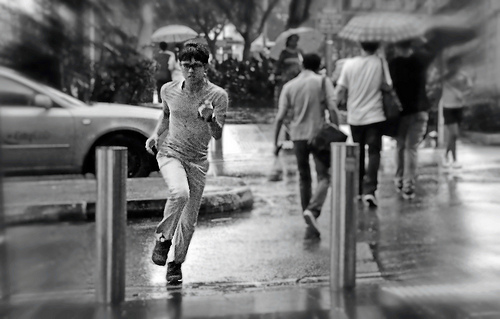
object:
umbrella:
[336, 13, 430, 45]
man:
[333, 38, 408, 209]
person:
[268, 32, 309, 87]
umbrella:
[269, 26, 325, 65]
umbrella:
[148, 24, 200, 44]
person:
[152, 39, 176, 105]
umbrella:
[421, 24, 478, 49]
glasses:
[180, 61, 207, 70]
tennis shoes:
[151, 236, 173, 266]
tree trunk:
[242, 40, 253, 67]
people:
[383, 30, 438, 201]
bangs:
[178, 46, 209, 63]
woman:
[429, 49, 476, 167]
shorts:
[441, 107, 465, 124]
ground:
[2, 115, 499, 319]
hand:
[196, 101, 214, 123]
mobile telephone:
[197, 98, 215, 120]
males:
[145, 43, 231, 290]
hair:
[177, 43, 209, 64]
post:
[98, 140, 136, 316]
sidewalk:
[0, 213, 499, 319]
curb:
[0, 173, 254, 222]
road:
[0, 123, 499, 296]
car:
[0, 57, 179, 179]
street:
[0, 114, 497, 318]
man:
[275, 50, 348, 239]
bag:
[312, 75, 347, 158]